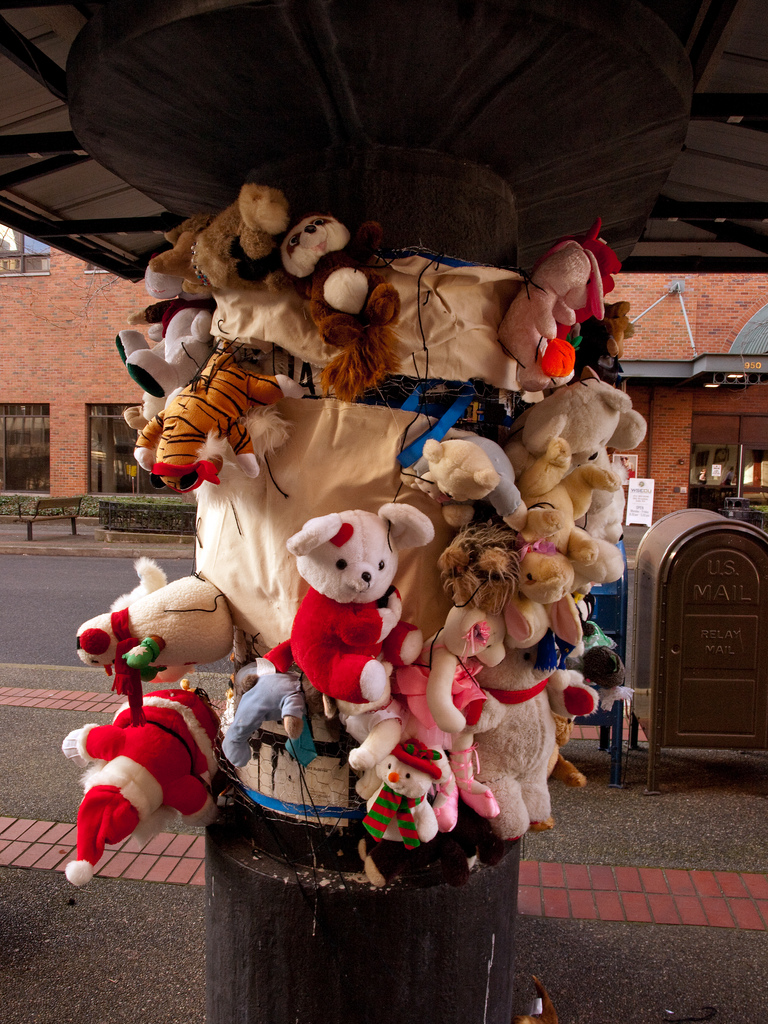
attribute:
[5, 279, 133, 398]
bricks — red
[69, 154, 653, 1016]
animals — stuffed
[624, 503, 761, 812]
mailbox — brown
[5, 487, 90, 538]
bench — empty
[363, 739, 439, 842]
snowman — small, stuffed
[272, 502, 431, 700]
mouse — red and white, stuffed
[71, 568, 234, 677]
penguin — white, stuffed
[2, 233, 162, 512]
building — red, brick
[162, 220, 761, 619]
bear — teddy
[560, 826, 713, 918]
tile — red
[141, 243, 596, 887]
stuffed animals — near eachother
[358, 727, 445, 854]
stuffed animal — snowman, in group